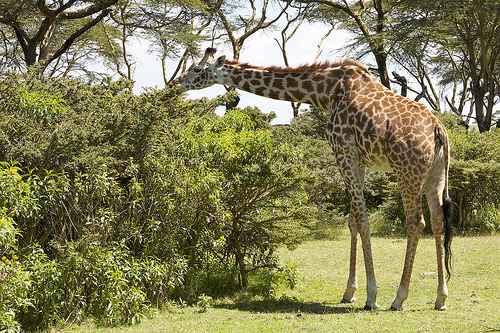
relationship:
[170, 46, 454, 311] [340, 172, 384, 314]
giraffe has leg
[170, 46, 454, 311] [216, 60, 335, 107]
giraffe has neck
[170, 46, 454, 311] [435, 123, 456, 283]
giraffe has tail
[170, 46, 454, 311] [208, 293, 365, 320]
giraffe has shadow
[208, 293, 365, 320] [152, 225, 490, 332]
shadow on ground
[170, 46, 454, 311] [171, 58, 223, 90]
giraffe has head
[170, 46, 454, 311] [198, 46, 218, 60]
giraffe has horns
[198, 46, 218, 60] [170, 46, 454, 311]
horns on giraffe